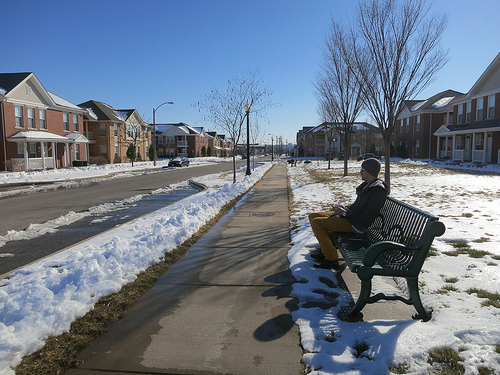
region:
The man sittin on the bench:
[308, 157, 385, 268]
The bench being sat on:
[333, 192, 446, 322]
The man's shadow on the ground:
[249, 258, 331, 340]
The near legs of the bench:
[345, 271, 433, 326]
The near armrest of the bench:
[362, 236, 419, 266]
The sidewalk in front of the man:
[64, 163, 306, 373]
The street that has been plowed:
[0, 158, 252, 277]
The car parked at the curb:
[167, 152, 192, 169]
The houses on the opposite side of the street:
[1, 67, 231, 174]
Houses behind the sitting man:
[291, 42, 498, 165]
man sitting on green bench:
[295, 134, 465, 343]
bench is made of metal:
[337, 183, 450, 335]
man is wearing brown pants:
[294, 154, 394, 285]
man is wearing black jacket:
[342, 155, 391, 263]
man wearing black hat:
[356, 152, 386, 190]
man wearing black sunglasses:
[353, 165, 382, 181]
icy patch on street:
[1, 180, 213, 272]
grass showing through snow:
[76, 150, 498, 360]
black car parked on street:
[168, 154, 203, 174]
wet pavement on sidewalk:
[85, 180, 261, 369]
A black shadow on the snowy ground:
[262, 242, 386, 365]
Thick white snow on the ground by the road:
[76, 228, 148, 282]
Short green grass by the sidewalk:
[32, 299, 104, 370]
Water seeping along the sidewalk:
[101, 279, 175, 369]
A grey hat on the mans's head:
[357, 158, 387, 178]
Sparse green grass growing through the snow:
[422, 345, 467, 372]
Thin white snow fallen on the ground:
[433, 169, 489, 229]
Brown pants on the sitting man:
[305, 209, 359, 260]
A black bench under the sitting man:
[344, 205, 441, 319]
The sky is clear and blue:
[25, 9, 293, 88]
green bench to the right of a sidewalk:
[330, 186, 443, 321]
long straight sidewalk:
[71, 160, 308, 374]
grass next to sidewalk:
[16, 190, 257, 372]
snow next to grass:
[0, 155, 275, 374]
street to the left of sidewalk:
[1, 150, 261, 274]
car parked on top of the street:
[167, 156, 182, 168]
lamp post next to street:
[151, 100, 179, 166]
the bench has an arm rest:
[365, 238, 412, 268]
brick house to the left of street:
[0, 72, 92, 172]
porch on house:
[9, 130, 66, 171]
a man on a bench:
[287, 135, 462, 356]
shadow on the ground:
[237, 242, 407, 373]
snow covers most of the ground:
[28, 132, 495, 373]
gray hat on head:
[356, 153, 384, 185]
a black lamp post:
[240, 87, 256, 175]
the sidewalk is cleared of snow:
[64, 156, 303, 370]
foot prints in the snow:
[291, 267, 341, 332]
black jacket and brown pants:
[303, 180, 405, 272]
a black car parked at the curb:
[167, 141, 196, 173]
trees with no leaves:
[313, 90, 423, 207]